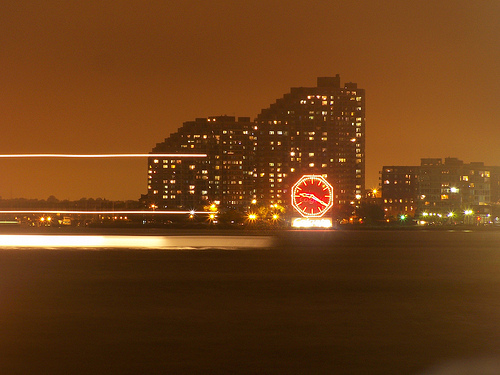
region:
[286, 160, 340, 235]
a bright city light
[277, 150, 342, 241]
a shining logo for a hotel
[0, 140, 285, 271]
blurring car lights on a road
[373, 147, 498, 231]
tall buildings in a desert environment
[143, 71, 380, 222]
large hotels extending into the sky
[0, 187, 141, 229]
city lights peaking through some haze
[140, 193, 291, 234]
streetlights in a parking lot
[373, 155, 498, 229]
Building with lights on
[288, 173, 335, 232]
Clock made of lights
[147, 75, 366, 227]
Building with lights on behind the clock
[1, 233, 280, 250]
Reflection in the water of lights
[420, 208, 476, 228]
Street lights next to a building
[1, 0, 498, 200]
Brown sky behind buildings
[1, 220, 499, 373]
Water in front of buildings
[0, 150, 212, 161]
Light streak in the sky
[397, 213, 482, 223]
Green and red traffic lights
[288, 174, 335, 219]
Octagonal red light clock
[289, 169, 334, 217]
The clock in front of the building.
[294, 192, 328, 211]
The hands of the clock.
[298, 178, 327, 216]
The lines on the clock.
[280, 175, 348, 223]
red clock lit up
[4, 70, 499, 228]
Buildings in the background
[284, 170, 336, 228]
Big clock with lights on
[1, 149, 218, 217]
two lines of light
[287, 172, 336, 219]
Long and short hand of the clock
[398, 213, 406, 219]
green light is on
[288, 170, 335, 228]
Rectangular light below the clock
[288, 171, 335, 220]
Big illuminated clock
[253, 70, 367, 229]
Tall building behind the clock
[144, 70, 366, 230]
Two tall buildings behind the clock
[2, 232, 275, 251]
Reflection of light in the water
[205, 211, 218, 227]
lights glaring from a distance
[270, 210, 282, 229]
lights glaring from a distance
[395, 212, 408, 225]
lights glaring from a distance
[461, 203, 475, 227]
lights glaring from a distance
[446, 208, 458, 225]
lights glaring from a distance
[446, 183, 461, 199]
lights glaring from a distance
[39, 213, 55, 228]
lights glaring from a distance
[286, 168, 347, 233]
a huge red clock in front of a building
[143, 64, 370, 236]
a tall and wide building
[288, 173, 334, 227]
round red clock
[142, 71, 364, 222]
big building with lights on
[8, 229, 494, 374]
large pavement highway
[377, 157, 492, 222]
small building with lights on in the background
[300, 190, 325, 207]
white clock hands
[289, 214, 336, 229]
white base of red clock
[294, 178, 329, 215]
yellow clock lines that show hours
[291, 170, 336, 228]
red and white with neon lights clock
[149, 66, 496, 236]
two buildings with lights on in the night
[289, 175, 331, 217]
clock is lit up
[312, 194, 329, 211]
minute hand on clock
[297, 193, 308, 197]
hour hand on clock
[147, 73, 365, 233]
building in the distance